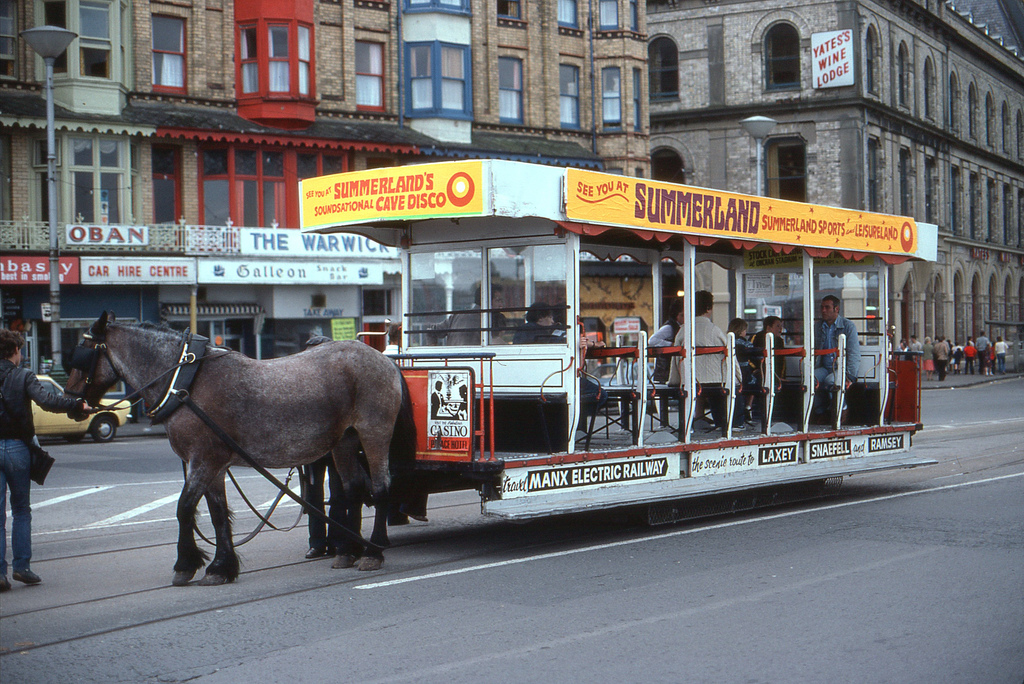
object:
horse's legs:
[195, 462, 239, 588]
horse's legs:
[352, 429, 396, 571]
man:
[0, 324, 71, 592]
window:
[76, 14, 124, 80]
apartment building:
[0, 0, 647, 217]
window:
[561, 64, 581, 132]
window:
[288, 22, 314, 94]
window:
[262, 16, 295, 94]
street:
[0, 428, 1024, 667]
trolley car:
[351, 148, 911, 504]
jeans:
[0, 444, 38, 588]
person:
[963, 340, 977, 375]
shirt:
[964, 346, 977, 358]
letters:
[808, 37, 856, 87]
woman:
[673, 289, 732, 438]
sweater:
[677, 316, 738, 383]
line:
[359, 511, 814, 589]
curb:
[922, 370, 1021, 391]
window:
[485, 57, 524, 122]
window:
[592, 59, 627, 135]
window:
[750, 19, 799, 91]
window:
[640, 40, 692, 111]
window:
[854, 11, 893, 101]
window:
[898, 40, 911, 105]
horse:
[63, 317, 412, 592]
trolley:
[105, 160, 918, 539]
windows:
[188, 146, 231, 227]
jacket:
[6, 363, 67, 439]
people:
[667, 289, 752, 428]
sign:
[807, 29, 858, 90]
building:
[662, 6, 1020, 352]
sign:
[67, 224, 148, 247]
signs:
[555, 183, 914, 252]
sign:
[294, 166, 486, 219]